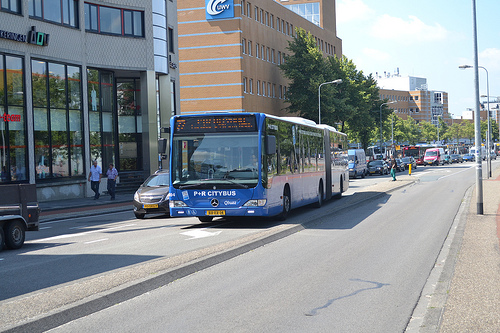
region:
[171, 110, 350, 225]
blue bus on street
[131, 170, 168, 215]
black car on street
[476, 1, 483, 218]
grey metal electrical pole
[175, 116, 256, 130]
electronic destination sign on bus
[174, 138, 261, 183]
wind shield on bus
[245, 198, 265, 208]
head light on bus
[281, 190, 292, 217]
black tire on bus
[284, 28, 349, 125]
tree with green leaves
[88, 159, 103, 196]
man wearing white shirt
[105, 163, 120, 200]
man walking on sidewalk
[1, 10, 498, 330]
Large multi-color bus driving down street.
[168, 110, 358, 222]
Big windshield on large bus.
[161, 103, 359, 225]
Windows on side of large bus.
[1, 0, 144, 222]
2 men walking down street beside each other.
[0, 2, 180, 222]
Tall building with windows and name on building.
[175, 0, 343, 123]
Tall brown building with blue and white sign on side.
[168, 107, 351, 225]
Bus with electric sign on front at top.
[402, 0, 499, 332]
Tall grey poles with street lights on sidewalk.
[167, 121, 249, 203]
Large bus on the pavement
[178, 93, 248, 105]
Long blue line on a brick building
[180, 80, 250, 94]
Long blue line on a brick building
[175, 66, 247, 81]
Long blue line on a brick building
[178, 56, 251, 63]
Long blue line on a brick building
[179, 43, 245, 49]
Long blue line on a brick building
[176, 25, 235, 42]
Long blue line on a brick building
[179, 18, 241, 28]
Long blue line on a brick building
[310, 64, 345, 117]
Large silver and white light post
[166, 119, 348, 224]
two car bus on the street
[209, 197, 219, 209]
brand on the bus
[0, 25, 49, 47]
business sign on the building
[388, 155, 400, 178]
a person on the street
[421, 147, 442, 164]
a pink van on the street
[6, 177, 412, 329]
a concrete median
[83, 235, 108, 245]
white line on the asphalt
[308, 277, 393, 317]
patch on the street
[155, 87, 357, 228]
City bus on the street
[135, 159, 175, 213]
car next to a bus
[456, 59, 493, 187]
light on a pole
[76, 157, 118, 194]
two people walking together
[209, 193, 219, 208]
Mercedes Benz Logo on the bus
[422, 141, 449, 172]
Red Van on the street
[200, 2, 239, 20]
blue sign on a building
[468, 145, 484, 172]
stickers on a pole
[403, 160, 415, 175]
yellow pole on the stret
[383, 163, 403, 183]
man wearing green pants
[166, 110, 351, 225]
a blue public service bus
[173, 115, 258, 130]
an electronic bus destination sign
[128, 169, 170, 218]
a grey car on street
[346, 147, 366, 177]
a blue van parked on street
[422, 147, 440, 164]
a red van in street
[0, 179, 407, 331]
a raised street median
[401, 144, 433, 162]
a red public service bus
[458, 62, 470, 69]
an overhead street light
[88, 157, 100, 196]
a person walking on sidewalk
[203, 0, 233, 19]
a business logo sign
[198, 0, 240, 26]
blue and white sign on building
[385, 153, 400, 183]
man wearing green pants crossing street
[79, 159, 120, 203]
two men walking down sidewalk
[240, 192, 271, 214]
left headlight of blue bus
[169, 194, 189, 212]
right headlight of blue bus